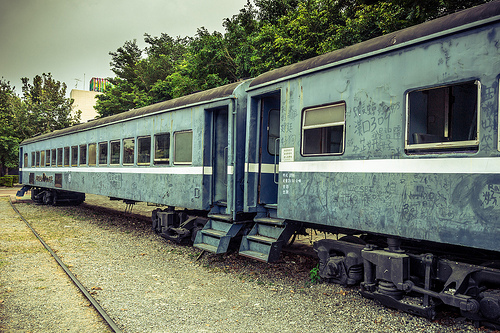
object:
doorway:
[192, 105, 236, 255]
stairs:
[238, 204, 292, 266]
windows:
[172, 129, 194, 166]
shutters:
[300, 103, 346, 131]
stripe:
[278, 157, 500, 175]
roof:
[245, 0, 500, 93]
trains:
[15, 16, 500, 329]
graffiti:
[346, 99, 401, 147]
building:
[64, 77, 118, 126]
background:
[0, 46, 82, 124]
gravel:
[77, 205, 115, 229]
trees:
[279, 0, 340, 59]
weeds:
[307, 264, 321, 284]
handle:
[273, 138, 279, 187]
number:
[371, 117, 378, 133]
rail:
[8, 200, 122, 333]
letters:
[282, 179, 286, 183]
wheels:
[317, 245, 363, 290]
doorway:
[237, 89, 282, 264]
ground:
[145, 284, 299, 332]